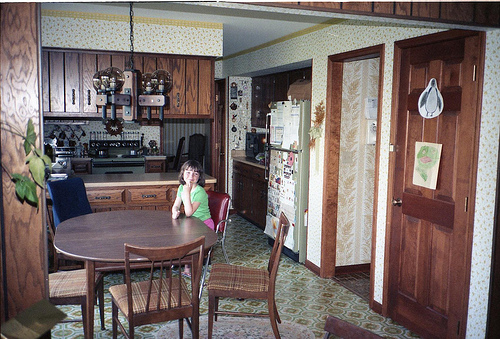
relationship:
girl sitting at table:
[163, 160, 219, 232] [53, 208, 219, 337]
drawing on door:
[417, 77, 446, 124] [383, 32, 486, 338]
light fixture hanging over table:
[90, 3, 176, 125] [41, 197, 223, 337]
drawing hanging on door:
[417, 77, 446, 124] [383, 32, 486, 338]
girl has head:
[163, 160, 219, 232] [177, 161, 203, 186]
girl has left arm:
[163, 160, 219, 232] [181, 180, 206, 219]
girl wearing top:
[163, 160, 219, 232] [176, 184, 212, 221]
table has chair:
[53, 208, 219, 337] [206, 212, 296, 338]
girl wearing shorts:
[163, 160, 219, 232] [200, 217, 216, 234]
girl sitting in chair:
[163, 160, 219, 232] [200, 191, 233, 300]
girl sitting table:
[163, 160, 219, 232] [41, 197, 223, 337]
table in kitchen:
[41, 197, 223, 337] [6, 7, 493, 336]